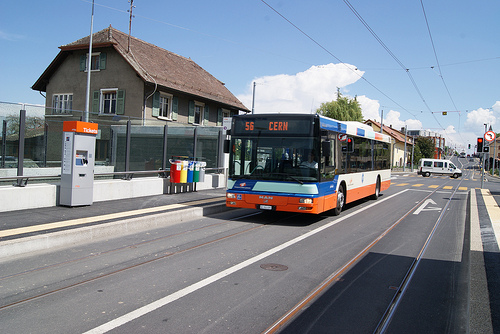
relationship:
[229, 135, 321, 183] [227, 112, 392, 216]
window on front of bus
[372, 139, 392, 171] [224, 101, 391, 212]
window on side of bus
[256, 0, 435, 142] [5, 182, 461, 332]
wires above street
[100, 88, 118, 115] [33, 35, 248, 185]
window on house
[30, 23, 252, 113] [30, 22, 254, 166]
roof on building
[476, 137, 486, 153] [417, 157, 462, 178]
light next to car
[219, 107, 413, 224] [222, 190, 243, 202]
bus has headlight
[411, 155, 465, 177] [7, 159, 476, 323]
car on street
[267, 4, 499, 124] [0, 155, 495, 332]
cables above ground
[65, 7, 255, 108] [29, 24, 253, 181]
roof of building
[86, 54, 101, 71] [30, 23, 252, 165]
window on building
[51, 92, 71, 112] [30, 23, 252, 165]
window on building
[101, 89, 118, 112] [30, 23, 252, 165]
window on building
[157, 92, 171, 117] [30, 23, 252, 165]
window on building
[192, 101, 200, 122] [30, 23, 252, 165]
window on building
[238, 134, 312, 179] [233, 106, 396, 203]
window of bus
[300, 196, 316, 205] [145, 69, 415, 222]
headlight of bus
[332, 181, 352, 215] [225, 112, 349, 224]
wheel of bus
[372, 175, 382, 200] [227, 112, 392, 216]
wheel of bus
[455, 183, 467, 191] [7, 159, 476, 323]
stripe in street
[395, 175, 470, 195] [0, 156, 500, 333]
yellow lines on road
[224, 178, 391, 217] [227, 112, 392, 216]
stripe on bottom of bus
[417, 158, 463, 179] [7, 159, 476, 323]
car driving down street